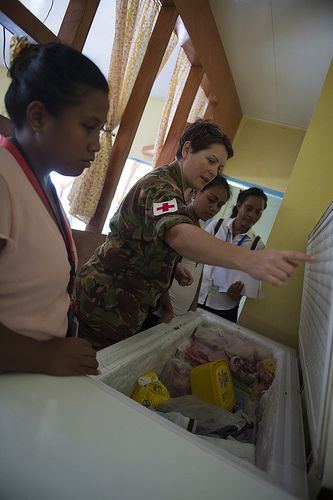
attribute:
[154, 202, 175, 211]
cross — red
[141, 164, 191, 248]
sleeve — rolled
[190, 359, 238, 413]
container — plastic, yellow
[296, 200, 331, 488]
door — open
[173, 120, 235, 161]
hair — short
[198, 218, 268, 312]
shirt — white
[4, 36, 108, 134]
hair — black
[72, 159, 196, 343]
shirt — camoflauge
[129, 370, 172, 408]
bag — yellow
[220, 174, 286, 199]
edgeing — blue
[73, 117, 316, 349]
woman — pointing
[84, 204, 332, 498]
freezer — deep, open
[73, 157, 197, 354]
uniform — camoflauge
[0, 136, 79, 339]
shirt — pink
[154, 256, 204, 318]
shirt — white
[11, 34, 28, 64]
ribbon — yellow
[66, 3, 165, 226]
curtain — tied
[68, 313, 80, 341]
badge — hanging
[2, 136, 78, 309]
ribbon — red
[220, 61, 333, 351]
wall — yellow